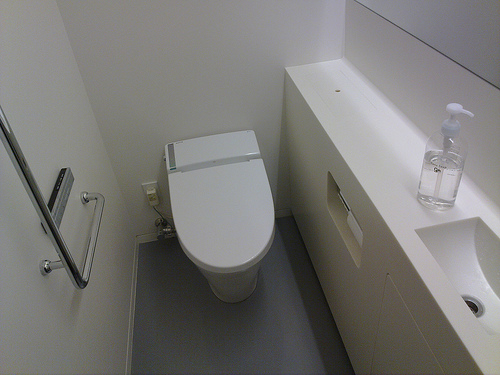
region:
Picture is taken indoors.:
[9, 12, 498, 366]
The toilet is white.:
[132, 65, 274, 290]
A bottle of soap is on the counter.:
[415, 55, 460, 262]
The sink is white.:
[393, 188, 490, 339]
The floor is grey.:
[152, 302, 327, 346]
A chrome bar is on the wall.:
[17, 109, 144, 309]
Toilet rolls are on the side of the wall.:
[315, 164, 382, 289]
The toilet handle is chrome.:
[152, 118, 197, 209]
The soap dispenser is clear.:
[401, 83, 453, 223]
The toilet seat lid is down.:
[162, 118, 324, 315]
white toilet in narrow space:
[91, 70, 326, 321]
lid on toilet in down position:
[135, 95, 287, 315]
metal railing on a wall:
[0, 95, 115, 301]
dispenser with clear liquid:
[405, 81, 477, 211]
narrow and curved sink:
[410, 207, 495, 362]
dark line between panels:
[360, 5, 490, 95]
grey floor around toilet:
[126, 195, 326, 360]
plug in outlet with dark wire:
[131, 167, 178, 247]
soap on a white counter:
[357, 75, 487, 215]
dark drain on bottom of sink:
[446, 273, 491, 333]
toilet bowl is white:
[152, 135, 286, 324]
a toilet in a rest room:
[122, 101, 308, 319]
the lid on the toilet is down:
[152, 126, 293, 296]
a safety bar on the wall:
[2, 135, 132, 315]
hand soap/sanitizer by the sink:
[410, 72, 475, 223]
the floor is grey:
[181, 310, 231, 360]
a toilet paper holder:
[320, 175, 376, 265]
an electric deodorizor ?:
[127, 165, 157, 225]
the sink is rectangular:
[416, 205, 492, 370]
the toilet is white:
[115, 80, 315, 320]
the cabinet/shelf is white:
[322, 90, 373, 167]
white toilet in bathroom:
[122, 97, 299, 304]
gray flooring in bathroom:
[163, 318, 323, 363]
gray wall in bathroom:
[81, 12, 278, 109]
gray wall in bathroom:
[4, 24, 147, 134]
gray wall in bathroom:
[21, 305, 124, 362]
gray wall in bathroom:
[350, 29, 483, 81]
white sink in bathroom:
[382, 217, 497, 354]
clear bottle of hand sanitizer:
[416, 85, 493, 231]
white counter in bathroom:
[286, 69, 411, 163]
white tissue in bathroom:
[336, 201, 372, 256]